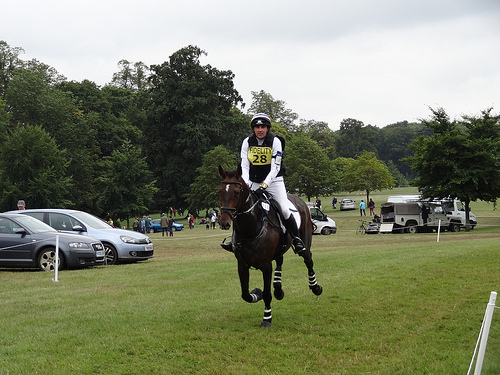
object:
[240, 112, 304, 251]
man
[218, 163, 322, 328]
horse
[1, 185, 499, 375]
field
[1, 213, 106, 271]
car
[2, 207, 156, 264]
car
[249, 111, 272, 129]
helmet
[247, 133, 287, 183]
vest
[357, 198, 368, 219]
person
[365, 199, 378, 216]
person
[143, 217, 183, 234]
car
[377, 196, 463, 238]
truck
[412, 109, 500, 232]
tree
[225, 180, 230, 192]
spot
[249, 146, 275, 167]
sign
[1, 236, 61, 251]
fence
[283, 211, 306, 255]
boot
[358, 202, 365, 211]
shirt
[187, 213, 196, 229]
person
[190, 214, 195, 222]
shirt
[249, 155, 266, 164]
number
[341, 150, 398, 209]
tree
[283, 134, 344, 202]
tree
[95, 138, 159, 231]
tree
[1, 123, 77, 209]
tree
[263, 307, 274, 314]
stripe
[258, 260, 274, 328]
leg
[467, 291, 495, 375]
fence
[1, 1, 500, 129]
sky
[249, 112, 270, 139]
head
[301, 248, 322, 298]
leg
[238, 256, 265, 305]
leg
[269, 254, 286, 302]
leg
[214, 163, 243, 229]
head